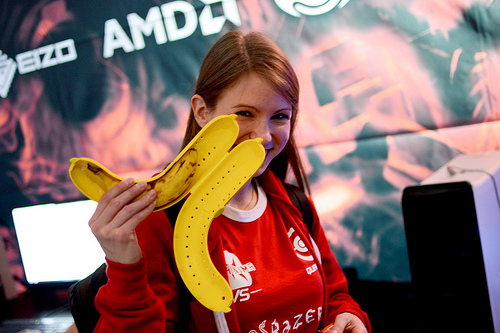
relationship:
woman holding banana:
[87, 24, 372, 333] [63, 107, 286, 319]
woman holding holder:
[87, 24, 372, 333] [193, 136, 230, 259]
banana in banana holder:
[85, 147, 198, 211] [67, 104, 264, 317]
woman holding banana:
[87, 24, 372, 333] [85, 146, 200, 206]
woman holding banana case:
[87, 24, 372, 333] [67, 112, 265, 314]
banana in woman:
[85, 147, 198, 211] [87, 24, 372, 333]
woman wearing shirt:
[87, 24, 372, 333] [205, 178, 335, 332]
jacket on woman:
[93, 173, 365, 331] [212, 47, 316, 331]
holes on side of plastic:
[175, 135, 220, 247] [190, 138, 247, 213]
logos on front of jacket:
[209, 221, 340, 331] [92, 167, 371, 333]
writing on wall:
[101, 2, 233, 54] [2, 1, 499, 273]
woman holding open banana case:
[61, 24, 352, 330] [180, 120, 230, 308]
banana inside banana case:
[155, 157, 195, 199] [180, 120, 230, 308]